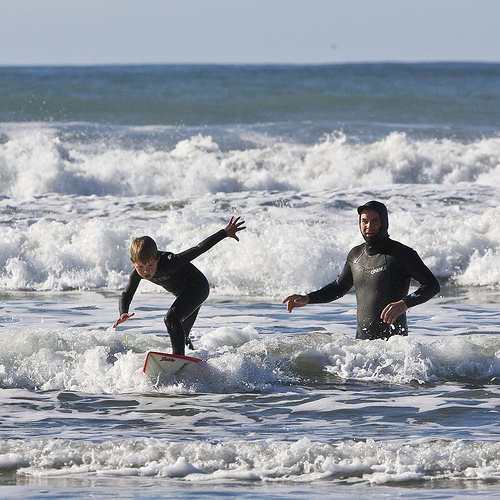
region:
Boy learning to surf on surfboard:
[97, 213, 256, 393]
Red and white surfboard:
[137, 345, 207, 382]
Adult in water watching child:
[279, 195, 444, 358]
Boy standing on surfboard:
[107, 215, 249, 387]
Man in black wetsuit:
[282, 194, 447, 347]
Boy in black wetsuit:
[93, 219, 253, 358]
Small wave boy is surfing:
[17, 322, 265, 409]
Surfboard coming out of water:
[134, 344, 216, 397]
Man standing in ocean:
[274, 196, 448, 347]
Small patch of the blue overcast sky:
[271, 18, 293, 44]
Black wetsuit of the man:
[356, 263, 391, 297]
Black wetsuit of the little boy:
[163, 273, 195, 293]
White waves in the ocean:
[71, 226, 101, 254]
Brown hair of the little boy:
[133, 243, 150, 257]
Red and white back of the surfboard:
[149, 349, 185, 374]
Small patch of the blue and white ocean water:
[320, 408, 345, 431]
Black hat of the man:
[365, 203, 385, 209]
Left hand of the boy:
[225, 215, 247, 242]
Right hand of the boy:
[113, 311, 138, 328]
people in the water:
[134, 138, 475, 390]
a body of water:
[72, 173, 415, 481]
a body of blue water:
[198, 127, 433, 476]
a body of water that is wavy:
[250, 277, 415, 476]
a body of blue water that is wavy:
[246, 261, 383, 464]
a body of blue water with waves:
[253, 164, 482, 446]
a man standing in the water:
[339, 133, 433, 498]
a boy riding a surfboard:
[94, 204, 296, 497]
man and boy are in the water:
[43, 192, 442, 381]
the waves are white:
[12, 415, 462, 490]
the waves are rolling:
[40, 111, 475, 325]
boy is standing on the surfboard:
[85, 190, 233, 387]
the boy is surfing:
[90, 170, 230, 397]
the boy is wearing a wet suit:
[95, 197, 260, 364]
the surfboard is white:
[110, 330, 250, 407]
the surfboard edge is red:
[112, 340, 209, 376]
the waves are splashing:
[75, 100, 470, 320]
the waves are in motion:
[0, 130, 480, 425]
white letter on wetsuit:
[371, 268, 375, 278]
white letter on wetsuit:
[372, 266, 377, 274]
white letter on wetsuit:
[375, 266, 380, 274]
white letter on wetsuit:
[379, 263, 383, 272]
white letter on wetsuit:
[380, 265, 387, 273]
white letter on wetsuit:
[165, 273, 171, 278]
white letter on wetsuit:
[161, 273, 168, 280]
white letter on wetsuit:
[157, 274, 162, 281]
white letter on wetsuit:
[153, 276, 161, 283]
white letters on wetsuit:
[368, 263, 387, 279]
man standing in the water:
[315, 203, 432, 370]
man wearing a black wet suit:
[286, 187, 444, 369]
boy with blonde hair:
[126, 234, 159, 278]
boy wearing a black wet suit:
[99, 229, 216, 356]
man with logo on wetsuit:
[362, 260, 390, 275]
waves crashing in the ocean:
[13, 123, 81, 197]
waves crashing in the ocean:
[86, 137, 158, 190]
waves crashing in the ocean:
[140, 142, 221, 200]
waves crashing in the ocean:
[200, 129, 313, 191]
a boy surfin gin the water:
[122, 228, 215, 355]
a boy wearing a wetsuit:
[86, 230, 199, 345]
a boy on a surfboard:
[104, 237, 234, 390]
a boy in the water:
[297, 201, 433, 349]